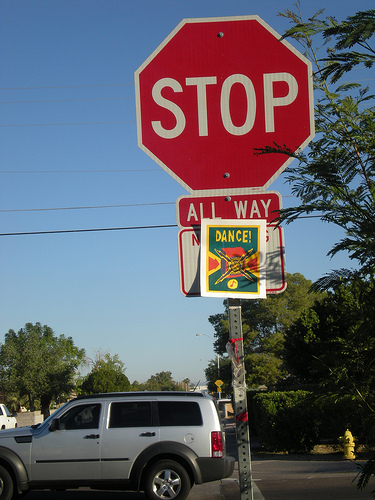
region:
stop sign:
[115, 4, 373, 185]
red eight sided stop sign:
[117, 6, 321, 229]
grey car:
[2, 376, 245, 498]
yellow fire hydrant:
[334, 424, 368, 469]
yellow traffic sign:
[209, 379, 229, 397]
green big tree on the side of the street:
[0, 313, 78, 422]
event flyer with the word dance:
[186, 212, 291, 317]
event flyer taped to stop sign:
[184, 213, 284, 318]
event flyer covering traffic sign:
[181, 206, 280, 304]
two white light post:
[179, 316, 231, 376]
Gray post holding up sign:
[226, 325, 253, 497]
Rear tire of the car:
[146, 459, 185, 496]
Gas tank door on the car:
[184, 432, 194, 443]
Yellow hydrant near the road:
[339, 431, 356, 459]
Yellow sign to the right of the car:
[214, 378, 225, 394]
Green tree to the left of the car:
[14, 341, 60, 389]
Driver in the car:
[87, 404, 101, 430]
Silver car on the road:
[8, 392, 224, 493]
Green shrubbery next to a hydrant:
[263, 395, 315, 441]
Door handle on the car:
[140, 431, 155, 435]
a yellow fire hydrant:
[336, 421, 360, 463]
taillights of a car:
[209, 429, 226, 457]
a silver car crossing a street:
[6, 388, 226, 489]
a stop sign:
[130, 21, 323, 184]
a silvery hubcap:
[153, 473, 183, 498]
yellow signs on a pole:
[211, 375, 228, 395]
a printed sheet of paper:
[197, 210, 268, 305]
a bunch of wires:
[1, 78, 131, 245]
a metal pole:
[224, 303, 261, 498]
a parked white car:
[0, 398, 22, 431]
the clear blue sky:
[12, 4, 72, 55]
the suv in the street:
[4, 390, 225, 495]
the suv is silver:
[4, 378, 231, 493]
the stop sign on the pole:
[122, 6, 332, 192]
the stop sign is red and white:
[129, 21, 324, 196]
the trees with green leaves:
[271, 312, 362, 370]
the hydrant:
[325, 429, 371, 472]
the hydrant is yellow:
[343, 420, 362, 465]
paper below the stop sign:
[187, 211, 286, 304]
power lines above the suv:
[6, 76, 161, 247]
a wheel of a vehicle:
[148, 459, 189, 495]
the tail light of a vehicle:
[208, 426, 226, 459]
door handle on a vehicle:
[84, 428, 103, 441]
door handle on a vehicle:
[139, 429, 156, 438]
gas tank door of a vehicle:
[180, 432, 199, 447]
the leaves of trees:
[305, 312, 346, 357]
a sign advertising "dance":
[197, 213, 274, 300]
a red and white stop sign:
[133, 11, 330, 193]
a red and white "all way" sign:
[175, 193, 285, 223]